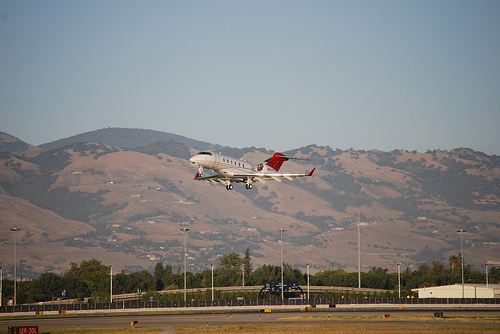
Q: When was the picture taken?
A: Day time.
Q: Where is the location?
A: The airport.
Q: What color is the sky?
A: Blue.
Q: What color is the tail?
A: Red.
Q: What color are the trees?
A: Green.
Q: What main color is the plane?
A: White.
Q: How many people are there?
A: None.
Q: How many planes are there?
A: One.